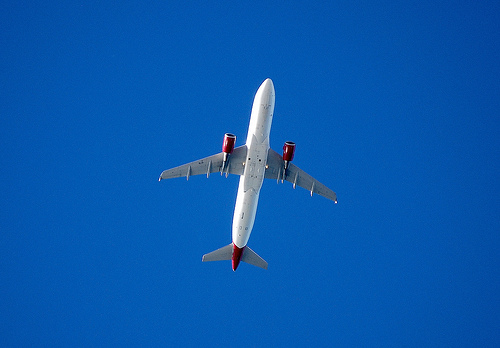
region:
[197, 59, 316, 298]
white commercial airliner flying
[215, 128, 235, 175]
red engine on right wing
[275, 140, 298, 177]
red engine on left wing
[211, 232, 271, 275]
tail of airplane painted red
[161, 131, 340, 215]
silver and red airplane wings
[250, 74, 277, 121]
white nose of airplane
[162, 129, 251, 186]
right wing of airplane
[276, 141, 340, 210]
left wing of airplane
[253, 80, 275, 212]
white fuselage of airplane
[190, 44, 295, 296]
red and white jet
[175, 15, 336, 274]
one plane in sky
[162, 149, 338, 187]
plane has white wings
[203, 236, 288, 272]
plane has white tail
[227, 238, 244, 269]
red rear of plane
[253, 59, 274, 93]
white tip of plane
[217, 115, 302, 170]
red engines on plane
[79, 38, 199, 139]
blue and clear sky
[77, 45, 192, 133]
no clouds in sky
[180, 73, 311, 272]
plane is in air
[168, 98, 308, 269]
white and red plane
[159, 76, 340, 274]
Plane flying in the air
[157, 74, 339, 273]
Airplane in the sky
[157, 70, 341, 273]
Airplane flying in the sky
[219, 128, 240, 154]
Red jet engine of an airplane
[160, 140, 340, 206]
Wings of an airplane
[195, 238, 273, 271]
Black wings of an airplane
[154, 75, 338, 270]
Airplane in a blue sky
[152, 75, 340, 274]
Model airplane on a blue background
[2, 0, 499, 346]
Large blue background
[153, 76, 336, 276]
White model airplane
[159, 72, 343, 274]
the plane is on the air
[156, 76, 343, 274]
the plane is in mid flight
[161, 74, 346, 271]
the plane is flying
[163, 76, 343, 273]
the plane is traveling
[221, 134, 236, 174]
the engine is under the wing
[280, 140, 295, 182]
the engine is under the wing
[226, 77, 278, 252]
the plane body is white in color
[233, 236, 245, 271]
the plane has a red tail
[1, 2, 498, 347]
the sky is blue in color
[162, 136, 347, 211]
the wings are grey in color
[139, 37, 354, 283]
Jumbo jet in the sky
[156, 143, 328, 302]
Jumbo jet in the sky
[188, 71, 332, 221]
Jumbo jet in the sky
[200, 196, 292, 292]
Jumbo jet in the sky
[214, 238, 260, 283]
red tail on a airplane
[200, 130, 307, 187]
two red engines on a airplane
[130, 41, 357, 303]
Jumbo jet in the sky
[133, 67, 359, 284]
Jumbo jet in the sky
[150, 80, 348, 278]
Jumbo jet in the sky